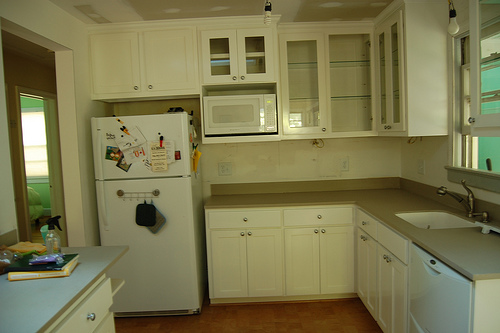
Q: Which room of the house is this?
A: It is a kitchen.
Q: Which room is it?
A: It is a kitchen.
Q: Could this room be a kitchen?
A: Yes, it is a kitchen.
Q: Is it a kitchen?
A: Yes, it is a kitchen.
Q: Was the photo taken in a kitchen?
A: Yes, it was taken in a kitchen.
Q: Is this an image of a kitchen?
A: Yes, it is showing a kitchen.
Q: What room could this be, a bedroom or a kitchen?
A: It is a kitchen.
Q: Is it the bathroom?
A: No, it is the kitchen.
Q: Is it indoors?
A: Yes, it is indoors.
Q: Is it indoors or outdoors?
A: It is indoors.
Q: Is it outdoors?
A: No, it is indoors.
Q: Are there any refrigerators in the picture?
A: Yes, there is a refrigerator.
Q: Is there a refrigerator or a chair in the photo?
A: Yes, there is a refrigerator.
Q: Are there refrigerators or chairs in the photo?
A: Yes, there is a refrigerator.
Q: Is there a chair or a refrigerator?
A: Yes, there is a refrigerator.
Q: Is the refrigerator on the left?
A: Yes, the refrigerator is on the left of the image.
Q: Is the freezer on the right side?
A: No, the freezer is on the left of the image.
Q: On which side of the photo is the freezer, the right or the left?
A: The freezer is on the left of the image.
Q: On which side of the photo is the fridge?
A: The fridge is on the left of the image.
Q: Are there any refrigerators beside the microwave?
A: Yes, there is a refrigerator beside the microwave.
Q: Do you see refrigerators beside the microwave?
A: Yes, there is a refrigerator beside the microwave.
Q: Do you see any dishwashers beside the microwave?
A: No, there is a refrigerator beside the microwave.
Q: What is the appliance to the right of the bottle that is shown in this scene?
A: The appliance is a refrigerator.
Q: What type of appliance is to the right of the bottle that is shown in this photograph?
A: The appliance is a refrigerator.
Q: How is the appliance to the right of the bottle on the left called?
A: The appliance is a refrigerator.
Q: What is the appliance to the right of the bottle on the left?
A: The appliance is a refrigerator.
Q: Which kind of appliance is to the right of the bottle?
A: The appliance is a refrigerator.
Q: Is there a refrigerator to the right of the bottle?
A: Yes, there is a refrigerator to the right of the bottle.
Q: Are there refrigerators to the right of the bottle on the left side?
A: Yes, there is a refrigerator to the right of the bottle.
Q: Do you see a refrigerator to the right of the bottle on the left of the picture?
A: Yes, there is a refrigerator to the right of the bottle.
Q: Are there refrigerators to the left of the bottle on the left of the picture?
A: No, the refrigerator is to the right of the bottle.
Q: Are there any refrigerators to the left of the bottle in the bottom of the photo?
A: No, the refrigerator is to the right of the bottle.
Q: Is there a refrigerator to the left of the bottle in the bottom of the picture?
A: No, the refrigerator is to the right of the bottle.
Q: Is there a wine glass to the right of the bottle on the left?
A: No, there is a refrigerator to the right of the bottle.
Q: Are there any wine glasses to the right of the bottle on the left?
A: No, there is a refrigerator to the right of the bottle.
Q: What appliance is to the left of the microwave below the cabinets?
A: The appliance is a refrigerator.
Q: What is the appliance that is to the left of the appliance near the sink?
A: The appliance is a refrigerator.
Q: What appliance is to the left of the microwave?
A: The appliance is a refrigerator.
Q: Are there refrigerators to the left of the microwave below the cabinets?
A: Yes, there is a refrigerator to the left of the microwave.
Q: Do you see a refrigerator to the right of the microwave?
A: No, the refrigerator is to the left of the microwave.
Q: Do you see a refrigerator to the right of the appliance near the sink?
A: No, the refrigerator is to the left of the microwave.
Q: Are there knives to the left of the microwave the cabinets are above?
A: No, there is a refrigerator to the left of the microwave.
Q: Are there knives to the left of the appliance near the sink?
A: No, there is a refrigerator to the left of the microwave.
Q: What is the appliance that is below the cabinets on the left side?
A: The appliance is a refrigerator.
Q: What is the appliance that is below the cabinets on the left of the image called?
A: The appliance is a refrigerator.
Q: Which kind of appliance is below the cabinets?
A: The appliance is a refrigerator.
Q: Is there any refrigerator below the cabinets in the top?
A: Yes, there is a refrigerator below the cabinets.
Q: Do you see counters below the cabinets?
A: No, there is a refrigerator below the cabinets.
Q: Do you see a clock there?
A: No, there are no clocks.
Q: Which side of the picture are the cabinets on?
A: The cabinets are on the left of the image.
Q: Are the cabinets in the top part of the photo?
A: Yes, the cabinets are in the top of the image.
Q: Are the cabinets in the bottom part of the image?
A: No, the cabinets are in the top of the image.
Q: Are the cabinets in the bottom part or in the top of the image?
A: The cabinets are in the top of the image.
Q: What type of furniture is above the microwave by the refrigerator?
A: The pieces of furniture are cabinets.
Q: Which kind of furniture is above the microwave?
A: The pieces of furniture are cabinets.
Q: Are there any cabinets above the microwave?
A: Yes, there are cabinets above the microwave.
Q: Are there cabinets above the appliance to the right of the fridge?
A: Yes, there are cabinets above the microwave.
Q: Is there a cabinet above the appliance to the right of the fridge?
A: Yes, there are cabinets above the microwave.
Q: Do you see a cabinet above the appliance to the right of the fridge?
A: Yes, there are cabinets above the microwave.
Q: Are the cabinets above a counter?
A: No, the cabinets are above the microwave.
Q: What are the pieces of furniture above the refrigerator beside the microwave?
A: The pieces of furniture are cabinets.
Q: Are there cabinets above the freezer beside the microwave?
A: Yes, there are cabinets above the refrigerator.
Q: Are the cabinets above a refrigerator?
A: Yes, the cabinets are above a refrigerator.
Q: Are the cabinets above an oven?
A: No, the cabinets are above a refrigerator.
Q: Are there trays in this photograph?
A: No, there are no trays.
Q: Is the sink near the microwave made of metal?
A: Yes, the sink is made of metal.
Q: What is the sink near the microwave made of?
A: The sink is made of metal.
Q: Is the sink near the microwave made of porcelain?
A: No, the sink is made of metal.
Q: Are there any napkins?
A: No, there are no napkins.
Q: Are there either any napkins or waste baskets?
A: No, there are no napkins or waste baskets.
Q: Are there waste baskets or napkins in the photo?
A: No, there are no napkins or waste baskets.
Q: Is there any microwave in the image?
A: Yes, there is a microwave.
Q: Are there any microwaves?
A: Yes, there is a microwave.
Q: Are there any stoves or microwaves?
A: Yes, there is a microwave.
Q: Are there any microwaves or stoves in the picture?
A: Yes, there is a microwave.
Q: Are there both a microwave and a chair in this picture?
A: No, there is a microwave but no chairs.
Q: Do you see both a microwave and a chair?
A: No, there is a microwave but no chairs.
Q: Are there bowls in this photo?
A: No, there are no bowls.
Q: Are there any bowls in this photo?
A: No, there are no bowls.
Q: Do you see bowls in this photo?
A: No, there are no bowls.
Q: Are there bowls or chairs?
A: No, there are no bowls or chairs.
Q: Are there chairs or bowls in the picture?
A: No, there are no bowls or chairs.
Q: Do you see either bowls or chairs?
A: No, there are no bowls or chairs.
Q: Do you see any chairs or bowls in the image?
A: No, there are no bowls or chairs.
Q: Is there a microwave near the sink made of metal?
A: Yes, there is a microwave near the sink.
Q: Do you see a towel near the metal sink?
A: No, there is a microwave near the sink.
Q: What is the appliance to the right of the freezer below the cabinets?
A: The appliance is a microwave.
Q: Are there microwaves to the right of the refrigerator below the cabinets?
A: Yes, there is a microwave to the right of the freezer.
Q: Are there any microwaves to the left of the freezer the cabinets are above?
A: No, the microwave is to the right of the refrigerator.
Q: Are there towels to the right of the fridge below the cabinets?
A: No, there is a microwave to the right of the refrigerator.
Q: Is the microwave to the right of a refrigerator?
A: Yes, the microwave is to the right of a refrigerator.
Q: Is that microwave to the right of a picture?
A: No, the microwave is to the right of a refrigerator.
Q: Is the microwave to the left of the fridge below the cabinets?
A: No, the microwave is to the right of the freezer.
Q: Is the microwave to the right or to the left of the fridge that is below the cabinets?
A: The microwave is to the right of the freezer.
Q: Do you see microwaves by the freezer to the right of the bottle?
A: Yes, there is a microwave by the fridge.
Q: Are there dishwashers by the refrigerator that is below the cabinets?
A: No, there is a microwave by the refrigerator.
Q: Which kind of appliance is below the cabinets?
A: The appliance is a microwave.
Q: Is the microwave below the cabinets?
A: Yes, the microwave is below the cabinets.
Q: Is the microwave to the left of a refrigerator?
A: No, the microwave is to the right of a refrigerator.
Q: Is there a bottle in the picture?
A: Yes, there is a bottle.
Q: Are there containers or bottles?
A: Yes, there is a bottle.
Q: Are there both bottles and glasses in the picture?
A: No, there is a bottle but no glasses.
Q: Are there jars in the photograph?
A: No, there are no jars.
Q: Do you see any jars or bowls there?
A: No, there are no jars or bowls.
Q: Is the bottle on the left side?
A: Yes, the bottle is on the left of the image.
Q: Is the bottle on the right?
A: No, the bottle is on the left of the image.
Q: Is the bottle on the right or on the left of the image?
A: The bottle is on the left of the image.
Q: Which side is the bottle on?
A: The bottle is on the left of the image.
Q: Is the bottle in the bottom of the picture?
A: Yes, the bottle is in the bottom of the image.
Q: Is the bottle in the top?
A: No, the bottle is in the bottom of the image.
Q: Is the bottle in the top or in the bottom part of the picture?
A: The bottle is in the bottom of the image.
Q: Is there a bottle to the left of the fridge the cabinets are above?
A: Yes, there is a bottle to the left of the refrigerator.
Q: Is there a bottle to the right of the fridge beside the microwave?
A: No, the bottle is to the left of the refrigerator.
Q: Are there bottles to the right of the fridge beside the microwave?
A: No, the bottle is to the left of the refrigerator.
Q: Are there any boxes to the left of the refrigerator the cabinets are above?
A: No, there is a bottle to the left of the freezer.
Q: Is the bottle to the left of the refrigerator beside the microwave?
A: Yes, the bottle is to the left of the freezer.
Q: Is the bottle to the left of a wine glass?
A: No, the bottle is to the left of the freezer.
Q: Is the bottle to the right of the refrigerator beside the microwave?
A: No, the bottle is to the left of the fridge.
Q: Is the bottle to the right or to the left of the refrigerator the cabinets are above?
A: The bottle is to the left of the fridge.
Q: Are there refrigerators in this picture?
A: Yes, there is a refrigerator.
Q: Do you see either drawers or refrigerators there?
A: Yes, there is a refrigerator.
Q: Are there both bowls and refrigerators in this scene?
A: No, there is a refrigerator but no bowls.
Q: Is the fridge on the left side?
A: Yes, the fridge is on the left of the image.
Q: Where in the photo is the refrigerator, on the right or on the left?
A: The refrigerator is on the left of the image.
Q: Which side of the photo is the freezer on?
A: The freezer is on the left of the image.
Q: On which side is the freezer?
A: The freezer is on the left of the image.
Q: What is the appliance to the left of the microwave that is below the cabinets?
A: The appliance is a refrigerator.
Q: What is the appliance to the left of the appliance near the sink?
A: The appliance is a refrigerator.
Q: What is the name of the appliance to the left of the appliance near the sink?
A: The appliance is a refrigerator.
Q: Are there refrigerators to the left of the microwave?
A: Yes, there is a refrigerator to the left of the microwave.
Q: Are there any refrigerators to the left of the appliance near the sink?
A: Yes, there is a refrigerator to the left of the microwave.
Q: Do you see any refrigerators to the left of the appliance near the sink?
A: Yes, there is a refrigerator to the left of the microwave.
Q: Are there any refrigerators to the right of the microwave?
A: No, the refrigerator is to the left of the microwave.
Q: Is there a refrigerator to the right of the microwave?
A: No, the refrigerator is to the left of the microwave.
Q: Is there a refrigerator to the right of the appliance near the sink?
A: No, the refrigerator is to the left of the microwave.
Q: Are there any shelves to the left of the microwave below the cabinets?
A: No, there is a refrigerator to the left of the microwave.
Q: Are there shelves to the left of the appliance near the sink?
A: No, there is a refrigerator to the left of the microwave.